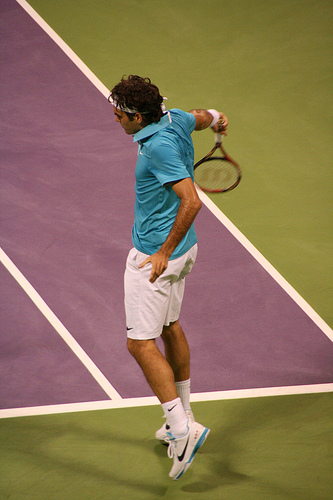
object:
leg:
[160, 284, 190, 421]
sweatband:
[112, 97, 169, 114]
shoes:
[154, 413, 210, 481]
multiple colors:
[0, 0, 330, 65]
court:
[0, 0, 333, 500]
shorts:
[123, 243, 198, 341]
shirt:
[130, 109, 197, 261]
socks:
[161, 377, 190, 438]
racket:
[193, 118, 243, 195]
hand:
[211, 111, 228, 136]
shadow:
[159, 327, 182, 379]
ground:
[0, 0, 333, 500]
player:
[106, 72, 227, 481]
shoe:
[168, 421, 210, 481]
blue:
[187, 426, 208, 466]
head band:
[108, 93, 167, 115]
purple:
[200, 342, 333, 384]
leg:
[126, 295, 188, 422]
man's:
[123, 244, 198, 340]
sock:
[161, 396, 187, 440]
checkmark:
[168, 404, 177, 412]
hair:
[107, 74, 164, 127]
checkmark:
[177, 434, 190, 462]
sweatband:
[207, 108, 219, 127]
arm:
[182, 109, 213, 131]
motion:
[168, 109, 228, 138]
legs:
[126, 290, 190, 419]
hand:
[138, 253, 168, 283]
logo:
[167, 404, 176, 412]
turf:
[0, 0, 332, 500]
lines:
[17, 1, 112, 103]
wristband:
[207, 109, 220, 128]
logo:
[199, 165, 232, 183]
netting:
[194, 160, 238, 188]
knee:
[126, 327, 144, 356]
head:
[111, 73, 163, 136]